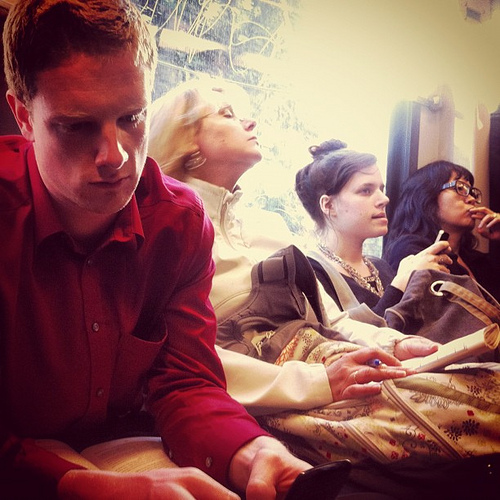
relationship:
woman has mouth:
[387, 160, 499, 285] [462, 206, 477, 215]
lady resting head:
[148, 75, 499, 490] [150, 75, 262, 176]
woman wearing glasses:
[387, 160, 499, 285] [446, 177, 485, 204]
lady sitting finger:
[148, 75, 500, 483] [341, 380, 384, 400]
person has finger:
[2, 1, 307, 499] [173, 459, 290, 499]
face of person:
[191, 88, 263, 165] [27, 64, 156, 209]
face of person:
[4, 9, 156, 213] [7, 108, 271, 408]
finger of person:
[349, 354, 470, 416] [136, 65, 496, 490]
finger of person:
[234, 455, 291, 496] [2, 1, 307, 499]